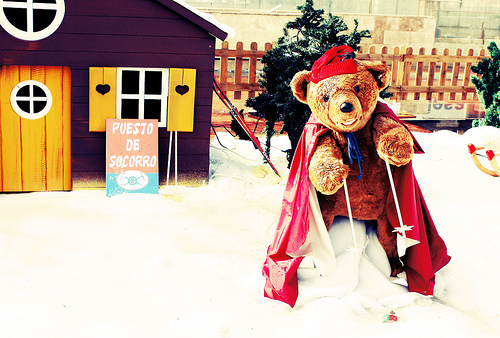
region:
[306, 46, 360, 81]
A red hat on a stuffed bear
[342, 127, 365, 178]
A blue string around a bear's neck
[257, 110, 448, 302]
A red cape on a stuffed bear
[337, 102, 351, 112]
A black nose on a bear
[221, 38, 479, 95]
A wooden fence behind a bear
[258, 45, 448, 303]
teddy bear with a red cape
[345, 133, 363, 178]
blue tie on red cape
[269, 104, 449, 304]
the bear's red cape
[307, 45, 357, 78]
the bear's red hat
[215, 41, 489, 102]
a brown, wood picket fence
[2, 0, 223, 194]
a small purple house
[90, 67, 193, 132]
window with yellow shutters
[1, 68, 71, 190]
yellow door on purple house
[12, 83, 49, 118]
round window on the door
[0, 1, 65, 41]
round window above the door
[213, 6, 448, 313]
this is a stuffed animal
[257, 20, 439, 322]
stuffed animal is a bear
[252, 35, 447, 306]
bear wearing a cape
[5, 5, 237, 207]
a house in the background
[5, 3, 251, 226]
the house is purple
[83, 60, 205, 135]
yellow shutters on the house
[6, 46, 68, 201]
a yellow door on the house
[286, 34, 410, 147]
bear wearing a red hat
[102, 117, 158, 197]
A sign written in Spanish.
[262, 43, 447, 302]
A teddy bear standing.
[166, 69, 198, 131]
A shutter with a heart carved in it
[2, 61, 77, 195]
A door with a circle window.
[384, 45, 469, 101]
A picket fence in the backround.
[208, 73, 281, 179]
Skis propped up on the side of the house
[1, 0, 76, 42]
A circle window on the house.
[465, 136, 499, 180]
Part of a sled.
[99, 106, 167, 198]
a signed written in Spanish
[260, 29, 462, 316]
a big teddy bear in the snow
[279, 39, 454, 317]
a teddy bear with ski poles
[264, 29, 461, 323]
a teddy bear wearing a red cape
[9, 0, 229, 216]
a purple Playhouse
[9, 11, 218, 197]
a purple Playhouse with yellow shutters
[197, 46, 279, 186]
a pair of skis leaning against the wall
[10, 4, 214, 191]
purple playhouse with a yellow front door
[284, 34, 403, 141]
a teddy bear wearing a red hat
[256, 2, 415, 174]
a teddy bear in front of a green tree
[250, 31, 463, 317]
a teddy bear wearing a red cap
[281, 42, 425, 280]
teddy bear color brown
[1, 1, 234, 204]
a toy house on the snow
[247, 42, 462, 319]
teddy bear on the snow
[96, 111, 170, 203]
sign in front of the house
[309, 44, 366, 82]
bear wearing a red hat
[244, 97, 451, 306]
teddy bear wearing a red cape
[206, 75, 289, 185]
ski poles on the house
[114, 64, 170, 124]
window on the house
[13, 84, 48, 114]
round window on the house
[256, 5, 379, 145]
tree in front of the fence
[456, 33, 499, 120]
tree in front of the fence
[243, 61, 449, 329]
bear standing in the snow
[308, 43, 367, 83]
red hat is worn by teddy bear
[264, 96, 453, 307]
red cloak is worn by teddy bear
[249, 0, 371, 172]
green tree is behind teddy bear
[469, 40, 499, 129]
green tree is to the right of teddy bear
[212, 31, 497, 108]
fence is behind house